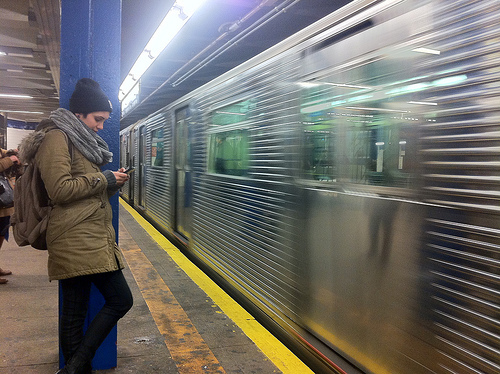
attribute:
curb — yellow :
[116, 183, 333, 368]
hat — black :
[42, 72, 129, 141]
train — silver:
[122, 77, 483, 360]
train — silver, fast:
[119, 0, 495, 370]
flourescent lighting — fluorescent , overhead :
[114, 0, 199, 95]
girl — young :
[3, 72, 143, 373]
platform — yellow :
[9, 180, 317, 372]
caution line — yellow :
[117, 196, 316, 372]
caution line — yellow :
[108, 210, 226, 372]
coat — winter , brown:
[30, 126, 125, 281]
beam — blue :
[52, 0, 125, 372]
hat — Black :
[67, 76, 112, 111]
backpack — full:
[6, 155, 61, 255]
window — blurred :
[187, 94, 272, 189]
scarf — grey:
[15, 104, 115, 167]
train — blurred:
[75, 8, 493, 371]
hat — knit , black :
[64, 69, 114, 121]